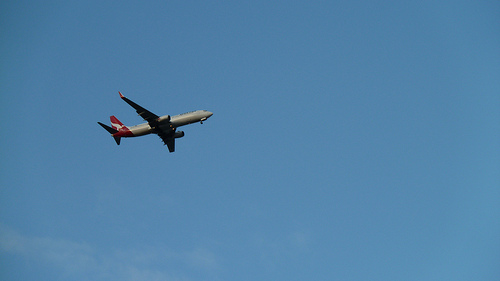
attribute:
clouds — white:
[42, 240, 226, 270]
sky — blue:
[18, 8, 480, 259]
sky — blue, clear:
[22, 13, 482, 278]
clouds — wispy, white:
[16, 230, 291, 278]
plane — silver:
[99, 89, 212, 154]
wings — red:
[115, 87, 178, 154]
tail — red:
[108, 113, 128, 134]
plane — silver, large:
[94, 86, 212, 152]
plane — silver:
[99, 93, 220, 156]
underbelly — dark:
[118, 100, 202, 147]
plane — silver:
[103, 90, 223, 152]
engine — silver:
[156, 113, 167, 125]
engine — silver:
[174, 130, 187, 140]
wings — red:
[121, 91, 176, 156]